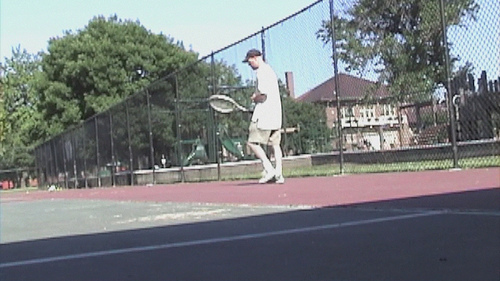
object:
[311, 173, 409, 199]
red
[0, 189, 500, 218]
side lines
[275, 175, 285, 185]
shoe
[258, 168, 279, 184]
shoe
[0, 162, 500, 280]
court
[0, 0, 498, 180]
leaves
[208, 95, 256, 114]
racket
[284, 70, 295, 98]
chimmney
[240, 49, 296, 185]
man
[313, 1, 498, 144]
tree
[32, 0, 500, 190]
fence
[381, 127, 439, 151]
garage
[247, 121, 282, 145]
shorts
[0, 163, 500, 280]
floor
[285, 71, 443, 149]
house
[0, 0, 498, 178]
background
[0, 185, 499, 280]
shade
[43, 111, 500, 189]
playground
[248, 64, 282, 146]
outfit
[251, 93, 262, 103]
hand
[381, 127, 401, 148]
door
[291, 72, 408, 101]
roof